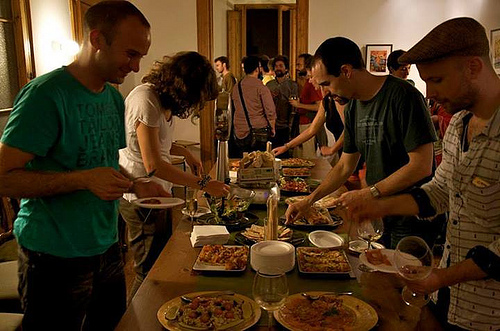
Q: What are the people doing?
A: Taking food.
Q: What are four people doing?
A: Taking food.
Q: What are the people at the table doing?
A: Taking food.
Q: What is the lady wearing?
A: A white shirt.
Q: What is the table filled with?
A: Food.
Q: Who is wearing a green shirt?
A: A man.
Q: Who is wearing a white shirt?
A: A woman.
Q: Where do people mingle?
A: In the doorway.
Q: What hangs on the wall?
A: Paintings.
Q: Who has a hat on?
A: A man.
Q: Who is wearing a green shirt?
A: A man.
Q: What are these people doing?
A: Choosing food from a buffet.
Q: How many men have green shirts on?
A: Two.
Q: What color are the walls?
A: White.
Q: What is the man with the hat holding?
A: A wine glass.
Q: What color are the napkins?
A: White.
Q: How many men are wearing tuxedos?
A: None.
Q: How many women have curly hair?
A: One.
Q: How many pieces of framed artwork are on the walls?
A: Two.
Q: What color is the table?
A: Brown.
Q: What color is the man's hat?
A: Brown.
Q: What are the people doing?
A: Eating.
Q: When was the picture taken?
A: Night time.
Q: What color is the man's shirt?
A: Green.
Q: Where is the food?
A: On the table.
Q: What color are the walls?
A: White.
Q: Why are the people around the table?
A: To get food.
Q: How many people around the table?
A: 5.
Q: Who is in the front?
A: Man in striped shirt.